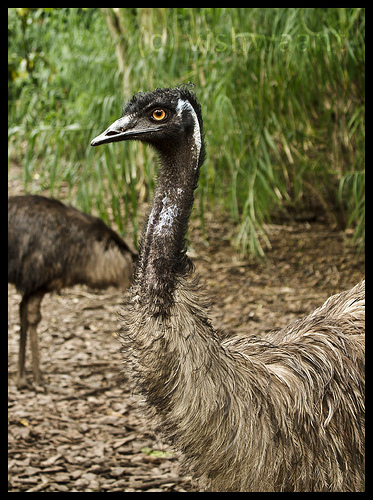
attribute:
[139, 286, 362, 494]
feathers — brown